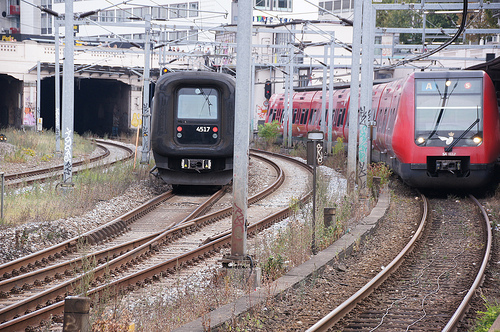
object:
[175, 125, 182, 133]
head lights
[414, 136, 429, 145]
head lights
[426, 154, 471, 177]
guard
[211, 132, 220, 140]
circles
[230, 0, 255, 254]
metal pole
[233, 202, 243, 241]
graffiti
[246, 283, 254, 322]
grass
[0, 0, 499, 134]
buildings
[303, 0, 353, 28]
cables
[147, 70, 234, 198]
train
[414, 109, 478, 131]
window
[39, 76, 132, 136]
train tunnel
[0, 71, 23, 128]
train tunnel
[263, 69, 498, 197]
train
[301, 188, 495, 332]
track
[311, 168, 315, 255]
pole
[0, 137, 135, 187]
tracks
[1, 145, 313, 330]
tracks